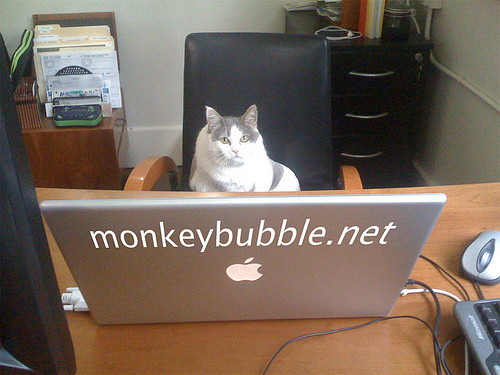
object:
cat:
[179, 100, 304, 195]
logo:
[222, 254, 266, 284]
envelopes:
[30, 22, 124, 115]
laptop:
[36, 193, 447, 324]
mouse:
[460, 223, 498, 286]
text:
[90, 218, 395, 252]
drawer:
[321, 23, 436, 167]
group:
[345, 0, 389, 41]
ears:
[238, 101, 263, 135]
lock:
[412, 50, 430, 92]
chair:
[122, 33, 366, 191]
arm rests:
[122, 154, 176, 191]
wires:
[468, 277, 494, 301]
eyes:
[214, 135, 258, 147]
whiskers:
[211, 144, 231, 171]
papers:
[34, 32, 107, 41]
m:
[85, 227, 121, 251]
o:
[117, 229, 137, 250]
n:
[137, 228, 158, 250]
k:
[158, 220, 176, 249]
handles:
[340, 154, 363, 193]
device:
[51, 95, 102, 126]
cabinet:
[18, 126, 122, 190]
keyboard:
[450, 285, 497, 374]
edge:
[449, 296, 499, 373]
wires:
[409, 269, 452, 373]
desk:
[0, 180, 497, 374]